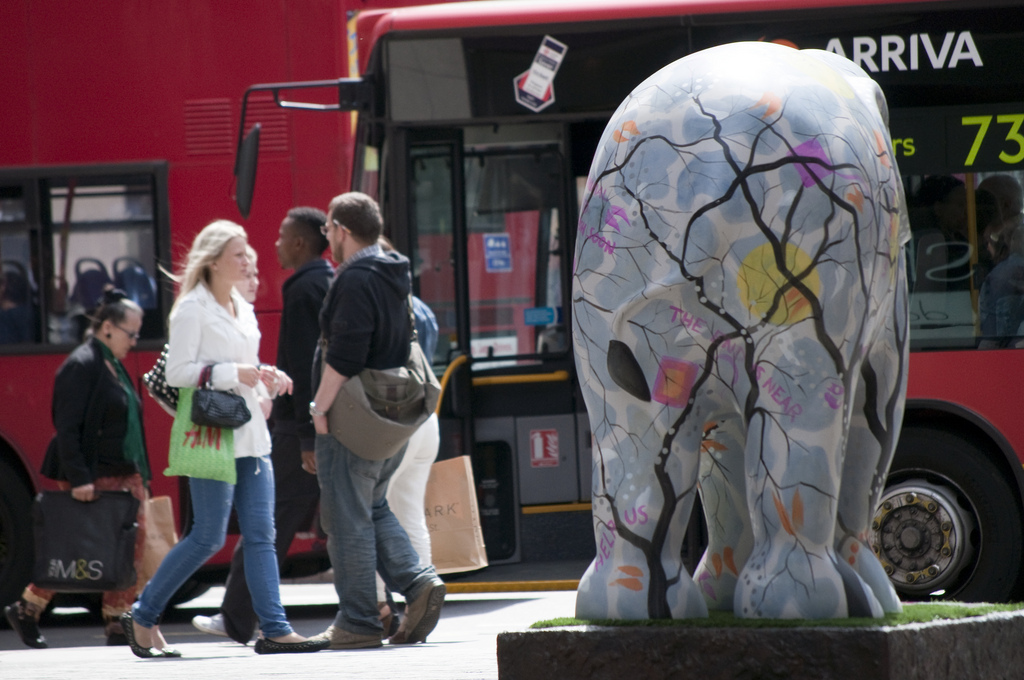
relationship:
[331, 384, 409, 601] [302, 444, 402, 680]
pants are grey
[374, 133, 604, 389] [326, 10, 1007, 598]
window on bus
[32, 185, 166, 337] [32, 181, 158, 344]
window on bus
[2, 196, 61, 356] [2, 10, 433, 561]
window on bus